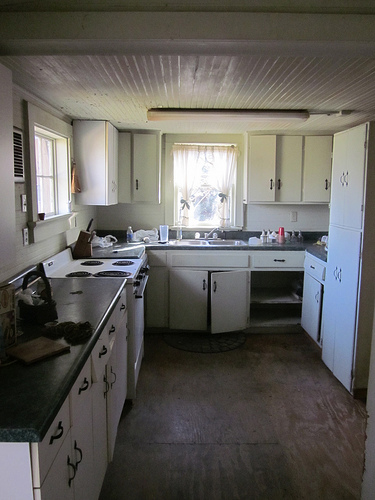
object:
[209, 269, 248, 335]
cabinet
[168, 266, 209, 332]
cabinet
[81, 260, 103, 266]
burner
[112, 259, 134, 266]
burner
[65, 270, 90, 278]
burner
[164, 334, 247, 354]
rug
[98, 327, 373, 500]
floor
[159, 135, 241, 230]
frame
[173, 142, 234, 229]
window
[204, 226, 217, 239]
faucet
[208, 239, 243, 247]
sink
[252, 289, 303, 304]
shelf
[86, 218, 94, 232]
knife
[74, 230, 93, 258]
knife block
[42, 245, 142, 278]
stove top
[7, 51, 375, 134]
ceiling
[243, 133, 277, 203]
cabinets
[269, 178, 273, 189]
handles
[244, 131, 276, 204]
cupboards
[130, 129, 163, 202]
cupboards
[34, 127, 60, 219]
window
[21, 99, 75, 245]
frame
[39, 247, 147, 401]
stove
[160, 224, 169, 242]
glass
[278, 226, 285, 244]
container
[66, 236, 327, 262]
counter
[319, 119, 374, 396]
cabinet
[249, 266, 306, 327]
cabinet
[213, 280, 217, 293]
handle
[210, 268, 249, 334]
door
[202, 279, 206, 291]
handle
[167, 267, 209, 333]
door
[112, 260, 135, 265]
jet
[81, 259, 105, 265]
jet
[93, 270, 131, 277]
jet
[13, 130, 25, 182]
vent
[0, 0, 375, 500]
kitchen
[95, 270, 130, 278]
burner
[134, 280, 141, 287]
handle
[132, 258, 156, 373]
oven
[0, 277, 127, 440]
counter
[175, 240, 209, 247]
sink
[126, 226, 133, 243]
bottle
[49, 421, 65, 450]
cabient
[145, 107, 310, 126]
light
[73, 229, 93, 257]
block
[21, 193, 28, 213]
switch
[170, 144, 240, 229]
curtain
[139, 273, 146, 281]
knob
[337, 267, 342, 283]
knob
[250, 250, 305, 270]
drawer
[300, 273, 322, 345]
door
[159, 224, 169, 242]
cup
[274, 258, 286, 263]
drawer handle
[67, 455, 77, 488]
handle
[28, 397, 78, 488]
cabinet